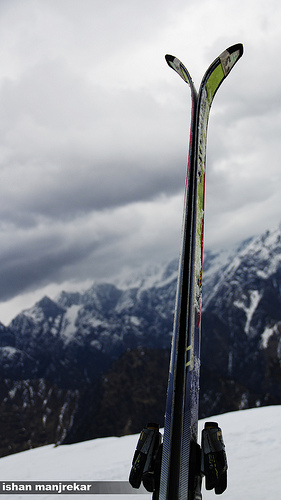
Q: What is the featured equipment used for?
A: Skiing.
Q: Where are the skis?
A: Standing in the snow.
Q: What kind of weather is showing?
A: Dark clouds.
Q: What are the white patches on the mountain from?
A: Snow.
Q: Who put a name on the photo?
A: The professional photographer.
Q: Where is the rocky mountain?
A: Behind the skis.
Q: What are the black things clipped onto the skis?
A: Boot mounts.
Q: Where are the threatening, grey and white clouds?
A: In the sky.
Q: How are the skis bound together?
A: With each one facing the opposite direction.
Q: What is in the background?
A: A chain of large, craggy mountains.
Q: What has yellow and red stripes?
A: Skis.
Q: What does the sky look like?
A: Very dark.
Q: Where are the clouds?
A: In the dark sky.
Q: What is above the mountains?
A: Very dark sky.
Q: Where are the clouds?
A: In the dark sky.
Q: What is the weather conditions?
A: Cloudy and dark.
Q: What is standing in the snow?
A: A pair of skis.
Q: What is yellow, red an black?
A: A pair of skis.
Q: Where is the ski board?
A: On the snow.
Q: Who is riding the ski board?
A: No one.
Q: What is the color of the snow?
A: White.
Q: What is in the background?
A: Mountains.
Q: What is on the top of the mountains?
A: Clouds and snow.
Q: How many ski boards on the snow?
A: Two.